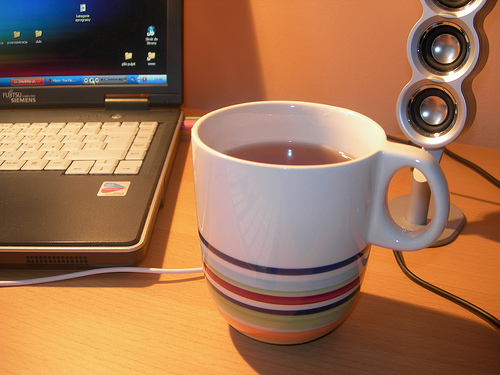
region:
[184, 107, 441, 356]
a mug with multi-colored stripes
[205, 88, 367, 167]
tea in a mug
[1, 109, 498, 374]
a pale wood table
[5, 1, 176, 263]
an open laptop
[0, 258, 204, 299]
a white cord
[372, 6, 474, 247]
a speaker on a support post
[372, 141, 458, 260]
a white handle on a mug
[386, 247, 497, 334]
a dark grey cord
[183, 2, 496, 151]
a peach colored wall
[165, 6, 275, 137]
the shadow of a monitro on a wall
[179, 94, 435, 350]
The cup has liquid.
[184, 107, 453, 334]
The cup is white.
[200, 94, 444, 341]
The cup has stripes.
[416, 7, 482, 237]
The speaker is silver.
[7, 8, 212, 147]
The computer is on.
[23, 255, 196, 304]
The cord is white.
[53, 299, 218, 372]
The desk is wood.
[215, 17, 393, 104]
The wall is tan.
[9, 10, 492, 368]
This is a workspace.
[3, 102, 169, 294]
The keyboard is grey and white.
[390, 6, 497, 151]
Silver speakers behind coffee cup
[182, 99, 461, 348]
Coffee mug with liquid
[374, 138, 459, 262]
Coffee mug handle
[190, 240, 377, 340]
Multicolored design on coffee mug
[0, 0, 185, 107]
Powered on laptop monitor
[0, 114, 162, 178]
White keyboard on laptop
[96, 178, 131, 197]
Logo sticker on laptop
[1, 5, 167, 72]
Desktop icons on laptop screen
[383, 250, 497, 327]
Black cord beside coffee mug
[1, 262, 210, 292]
White cup to the left of coffee mug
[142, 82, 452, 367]
a cup of coffee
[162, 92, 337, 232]
a cup of coffee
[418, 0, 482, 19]
the top part of a speaker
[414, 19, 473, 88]
the center circle of a speak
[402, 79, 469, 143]
the bottom circle of a speaker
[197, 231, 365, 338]
stripes on the bottom half of a cup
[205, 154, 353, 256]
the white upper half of a cup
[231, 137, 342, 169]
tea in a mug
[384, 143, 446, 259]
the white handle of a tea mug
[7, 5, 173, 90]
the lit up screen of a laptop monitor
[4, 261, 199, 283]
a white power cord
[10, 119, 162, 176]
white keys on a laptop keyboard